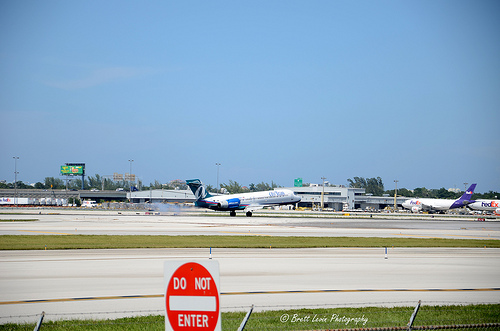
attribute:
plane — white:
[395, 179, 477, 218]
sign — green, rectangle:
[59, 161, 84, 177]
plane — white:
[188, 175, 297, 228]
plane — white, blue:
[180, 175, 302, 222]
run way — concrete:
[1, 246, 498, 321]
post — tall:
[9, 149, 21, 194]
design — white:
[184, 178, 209, 201]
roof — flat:
[276, 180, 367, 192]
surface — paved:
[208, 236, 429, 304]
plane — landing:
[182, 177, 302, 217]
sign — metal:
[145, 250, 235, 329]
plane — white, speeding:
[99, 164, 371, 219]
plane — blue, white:
[153, 171, 365, 232]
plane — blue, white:
[375, 177, 498, 238]